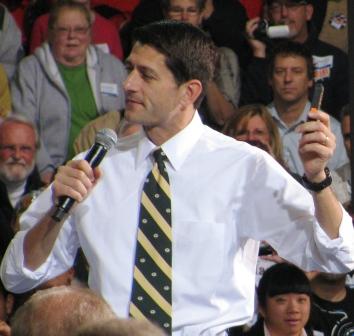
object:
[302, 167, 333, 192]
black-wrist watch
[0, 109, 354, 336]
white shirt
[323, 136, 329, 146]
man's-wedding band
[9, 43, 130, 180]
grey-hooded jacket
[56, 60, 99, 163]
woman's-green shirt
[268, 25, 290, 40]
open-silver camcorder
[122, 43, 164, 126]
caucasian-man's face